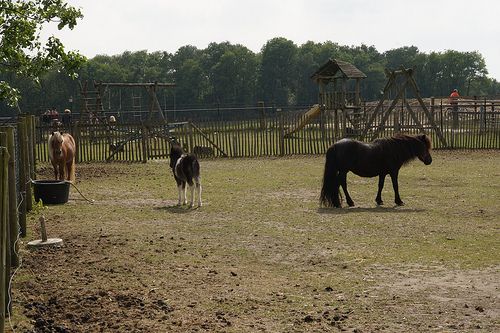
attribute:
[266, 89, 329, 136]
slide — yellow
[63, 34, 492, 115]
trees — green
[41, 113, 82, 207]
horse — brown, white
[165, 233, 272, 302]
ground — bare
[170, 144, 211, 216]
horse — black, white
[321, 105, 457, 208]
horse — brown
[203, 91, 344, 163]
fence — brown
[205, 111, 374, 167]
fence — tall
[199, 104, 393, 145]
fence — tall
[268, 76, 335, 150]
slide — yellow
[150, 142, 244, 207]
horse — brown, white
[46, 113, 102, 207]
horse — white, brown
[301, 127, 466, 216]
horse — black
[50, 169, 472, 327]
field — grass, mud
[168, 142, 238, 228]
horse — black, white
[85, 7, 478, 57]
sky — mostly white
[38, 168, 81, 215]
tub — large, black, round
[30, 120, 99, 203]
horse — brown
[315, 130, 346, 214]
horse tail — long, black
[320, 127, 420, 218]
horse — black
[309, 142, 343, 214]
tail — long, hairy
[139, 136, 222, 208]
horse — small, brown, white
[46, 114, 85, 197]
horse — brown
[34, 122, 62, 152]
mane — white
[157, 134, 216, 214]
horse — brown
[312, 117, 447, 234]
horse — brown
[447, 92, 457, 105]
top — orange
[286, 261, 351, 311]
grass — short, green, brown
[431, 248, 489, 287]
grass — short, green, brown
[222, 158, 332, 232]
grass — short, green, brown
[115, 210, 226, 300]
grass — short, green, brown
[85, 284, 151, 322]
grass — short, green, brown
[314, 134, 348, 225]
tail — long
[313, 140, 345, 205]
tail — long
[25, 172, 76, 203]
container — black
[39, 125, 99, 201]
pony — brown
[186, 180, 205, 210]
legs — white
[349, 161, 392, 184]
belly — bulky